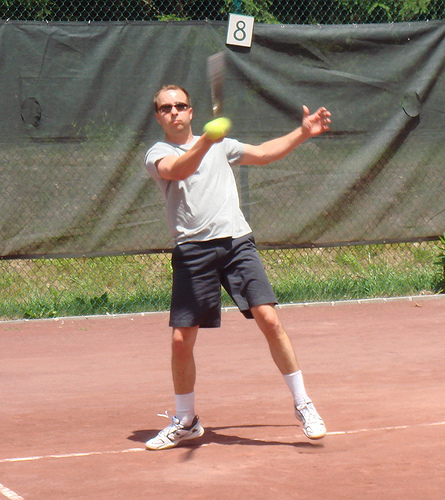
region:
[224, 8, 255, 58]
black number on white card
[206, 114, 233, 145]
yellow ball in the air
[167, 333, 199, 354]
knee on a man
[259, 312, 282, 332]
knee on a man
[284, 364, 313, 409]
white sock on an ankle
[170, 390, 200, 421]
white sock on an ankle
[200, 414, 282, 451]
shadow on the tennis court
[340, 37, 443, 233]
black mesh covering on the fence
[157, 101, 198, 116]
black sunglasses on a face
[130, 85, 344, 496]
a man swinging at a tennis ball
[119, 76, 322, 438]
this is a tennis player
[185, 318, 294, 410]
the legs are apart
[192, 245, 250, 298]
he is wearing shorts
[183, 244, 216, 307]
the short is black in color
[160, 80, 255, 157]
he is swinging a racket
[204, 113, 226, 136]
this is the ball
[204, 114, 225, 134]
the ball is on air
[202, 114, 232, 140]
the ball is green in color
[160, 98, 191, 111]
he is wearing goggles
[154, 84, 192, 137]
a goofy look on a man's face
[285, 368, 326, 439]
left foot lifted off of the court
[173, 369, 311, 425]
pair of white socks in use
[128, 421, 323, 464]
the shadow of a tennis player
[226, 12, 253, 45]
number 8 hanging on a fence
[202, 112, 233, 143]
the tennis ball in flight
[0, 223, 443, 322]
an area of grass and weeds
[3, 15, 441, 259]
dark cloth for vision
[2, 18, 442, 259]
a cloth background that is pourous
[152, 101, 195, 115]
a pair of sunglasses on the player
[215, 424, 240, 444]
shadow on the court.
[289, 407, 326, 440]
tennis shoe on man's foot.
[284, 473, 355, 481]
clay surface on court.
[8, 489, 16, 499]
white chalk on court.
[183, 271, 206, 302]
dark shorts on man.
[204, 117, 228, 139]
tennis ball in the air.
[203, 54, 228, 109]
racquet in man's hand.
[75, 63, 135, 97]
tarp on the fence.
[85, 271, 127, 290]
chain links on fence.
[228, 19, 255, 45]
number on the fence.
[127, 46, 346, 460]
A man swinging the tennis racket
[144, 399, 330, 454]
A pair of sneakers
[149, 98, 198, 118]
Sunglasses over man's eyes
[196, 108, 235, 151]
A round tennis ball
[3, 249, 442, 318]
Green grass behind the man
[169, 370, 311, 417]
A pair of white socks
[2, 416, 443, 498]
White lines on the court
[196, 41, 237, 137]
Tennis racket in motion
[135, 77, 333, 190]
Man has his arms raised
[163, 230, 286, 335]
A pair of black shorts